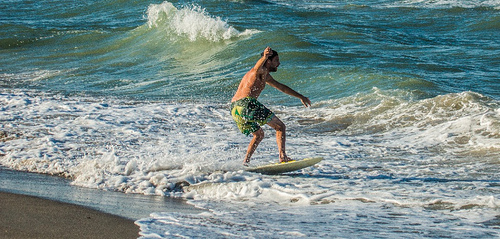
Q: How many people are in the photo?
A: One.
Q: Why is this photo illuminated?
A: Sunlight.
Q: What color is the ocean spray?
A: White.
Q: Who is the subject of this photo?
A: The surfer.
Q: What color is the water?
A: Blue.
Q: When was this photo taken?
A: During the day.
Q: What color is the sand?
A: Brown.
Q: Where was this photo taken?
A: At a beach.